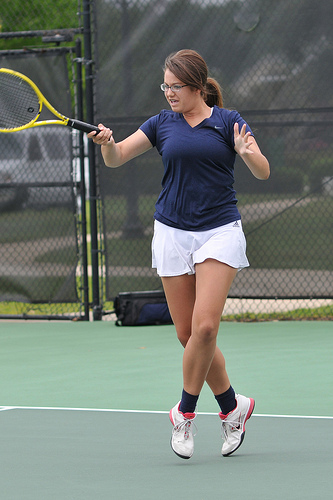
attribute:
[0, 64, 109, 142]
tennis racket — yellow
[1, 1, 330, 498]
fence — chain link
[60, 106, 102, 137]
handle — black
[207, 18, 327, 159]
fence — chain link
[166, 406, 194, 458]
shoe — white, pink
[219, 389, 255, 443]
shoe — pink, white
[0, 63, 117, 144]
racket — yellow with black handle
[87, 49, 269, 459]
girl — young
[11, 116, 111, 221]
vehicle — white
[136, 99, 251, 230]
shirt — blue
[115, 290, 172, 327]
bag — blue, black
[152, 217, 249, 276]
shorts — white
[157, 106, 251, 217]
shirt — blue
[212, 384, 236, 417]
sock — black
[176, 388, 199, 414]
sock — black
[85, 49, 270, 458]
woman — young